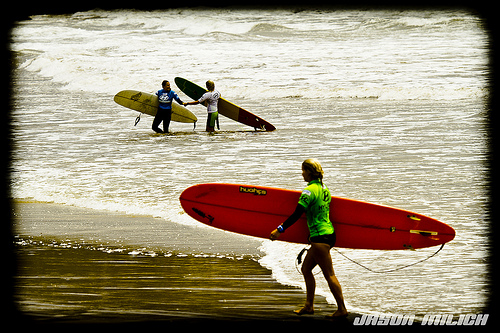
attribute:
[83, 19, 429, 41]
waves — small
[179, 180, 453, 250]
surfboard — red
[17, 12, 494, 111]
waves — white capped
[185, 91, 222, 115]
shirt — long sleeve, white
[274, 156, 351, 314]
person — wearing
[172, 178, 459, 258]
surfboard — red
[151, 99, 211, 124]
shirt — blue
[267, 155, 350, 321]
woman — surfer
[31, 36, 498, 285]
bubbles — white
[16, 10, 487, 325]
water — bubbly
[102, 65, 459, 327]
surfers — longboard 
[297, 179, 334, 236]
surf shirt — green, lime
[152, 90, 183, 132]
wetsuit — black, blue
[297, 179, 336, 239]
shirt — green